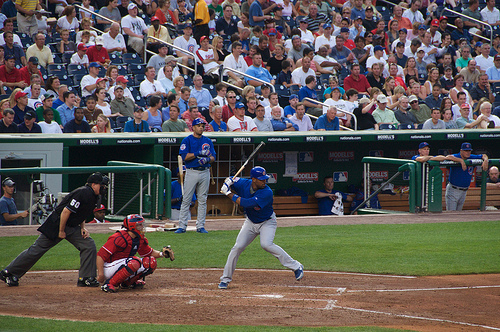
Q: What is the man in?
A: Uniform.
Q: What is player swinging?
A: Bat.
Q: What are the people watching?
A: Baseball.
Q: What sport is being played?
A: Baseball.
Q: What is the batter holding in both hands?
A: A bat.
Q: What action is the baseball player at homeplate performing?
A: Swinging the bat.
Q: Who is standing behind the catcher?
A: The umpire.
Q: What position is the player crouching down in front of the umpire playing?
A: Catcher.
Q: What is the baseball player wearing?
A: A blue and white uniform.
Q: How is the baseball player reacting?
A: Ready to swing the bat.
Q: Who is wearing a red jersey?
A: The baseball catcher.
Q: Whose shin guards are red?
A: The catcher.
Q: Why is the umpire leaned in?
A: To make the call.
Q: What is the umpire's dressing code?
A: Wearing a black shirt.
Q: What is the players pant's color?
A: Grey.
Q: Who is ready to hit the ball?
A: The baseball batter.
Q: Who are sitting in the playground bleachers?
A: Baseball fans.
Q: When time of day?
A: Daytime.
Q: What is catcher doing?
A: Squatting.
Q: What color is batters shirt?
A: Blue.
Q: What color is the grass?
A: Green.